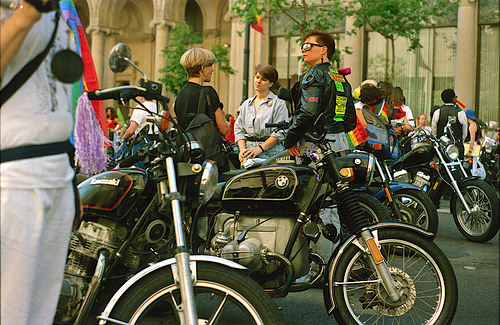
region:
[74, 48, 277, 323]
Kawasaki motorcycle for transportation.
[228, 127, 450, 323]
BMW motorcycle for transportation.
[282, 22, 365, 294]
Motorcycle rider talking with other people.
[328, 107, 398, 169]
Rainbow flag decorating one of the motorcycles.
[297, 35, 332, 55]
Sunglasses for eye protection.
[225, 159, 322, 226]
Motorcycle gas tank for fuel storage.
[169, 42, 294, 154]
Two women having a conversation.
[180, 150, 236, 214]
Motorcycle head lamp for riding at night.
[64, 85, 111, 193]
Pompom attached to the handle bars for decoration.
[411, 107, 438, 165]
Young girl taking in the experience of all the motorcycles.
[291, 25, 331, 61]
the head of a person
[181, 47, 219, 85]
the head of a person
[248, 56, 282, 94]
the head of a person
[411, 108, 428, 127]
the head of a person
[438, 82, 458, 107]
the head of a person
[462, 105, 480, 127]
the head of a person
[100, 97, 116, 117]
the head of a person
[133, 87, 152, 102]
the head of a person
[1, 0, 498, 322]
lots of motorcycle ladies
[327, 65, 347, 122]
patches on the woman's jacket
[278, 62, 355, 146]
she is wearing a leather jacket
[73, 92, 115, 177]
purple streamers on a bike handle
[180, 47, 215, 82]
one woman has blonde hair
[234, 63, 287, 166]
a woman wearing a blue shirt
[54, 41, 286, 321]
the motorcycle in the foreground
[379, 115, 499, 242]
a motorcycle in the background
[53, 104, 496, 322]
a large group of motorcycles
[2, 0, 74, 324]
a woman in the foreground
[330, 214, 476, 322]
Tire on a motorcycle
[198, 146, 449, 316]
Black motorcycle parked by a road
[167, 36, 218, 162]
Woman with blonde hair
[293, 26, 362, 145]
Woman in a leather jacket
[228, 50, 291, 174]
Woman with brown hair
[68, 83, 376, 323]
Two motorcycles parked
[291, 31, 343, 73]
Glasses on a woman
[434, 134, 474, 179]
Light on a motorcycle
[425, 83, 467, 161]
Person standing on a road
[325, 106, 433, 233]
Blue motorcycle on a road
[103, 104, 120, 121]
the head of a person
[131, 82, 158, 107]
the head of a person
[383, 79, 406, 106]
the head of a person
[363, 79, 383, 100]
the head of a person